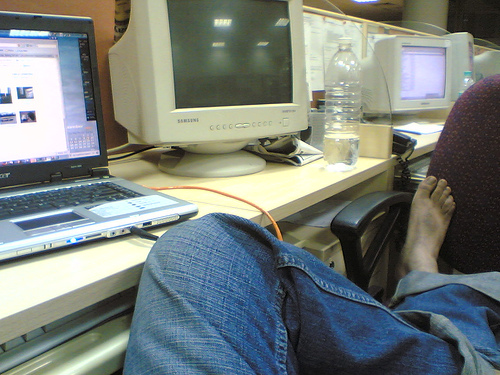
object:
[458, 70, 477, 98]
bottle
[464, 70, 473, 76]
cap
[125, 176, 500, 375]
person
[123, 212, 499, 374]
blue jeans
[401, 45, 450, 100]
monitor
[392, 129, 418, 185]
phone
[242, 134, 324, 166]
folded papers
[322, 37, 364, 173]
bottle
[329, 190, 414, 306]
handle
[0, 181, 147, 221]
key pad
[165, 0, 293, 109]
computer monitor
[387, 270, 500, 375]
cuffs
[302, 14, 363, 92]
papers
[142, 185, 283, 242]
orange cable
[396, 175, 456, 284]
barefoot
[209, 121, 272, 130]
buttons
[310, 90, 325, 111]
cork board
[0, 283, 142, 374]
keyboard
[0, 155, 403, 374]
shelf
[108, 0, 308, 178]
computer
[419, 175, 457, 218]
toes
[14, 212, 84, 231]
trackpad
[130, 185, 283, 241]
cable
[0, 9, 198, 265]
computer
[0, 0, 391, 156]
wall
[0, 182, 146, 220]
keys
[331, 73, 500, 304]
chair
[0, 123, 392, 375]
desk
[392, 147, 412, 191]
cord